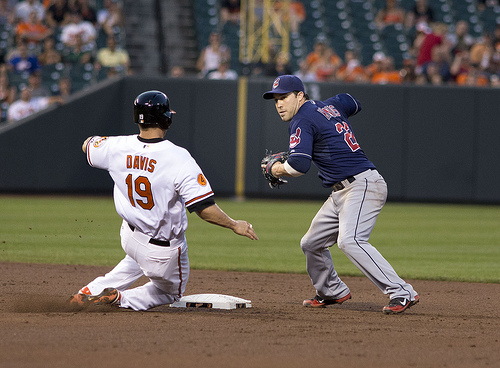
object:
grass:
[0, 190, 499, 285]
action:
[66, 73, 421, 316]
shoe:
[299, 288, 353, 310]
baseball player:
[257, 73, 421, 316]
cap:
[259, 73, 307, 101]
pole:
[232, 76, 249, 201]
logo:
[286, 126, 303, 149]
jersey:
[83, 132, 215, 242]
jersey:
[281, 92, 379, 190]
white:
[166, 291, 253, 312]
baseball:
[44, 55, 416, 332]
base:
[168, 291, 253, 310]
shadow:
[95, 301, 282, 321]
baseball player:
[62, 89, 258, 314]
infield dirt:
[0, 257, 499, 368]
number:
[123, 173, 138, 209]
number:
[130, 175, 155, 211]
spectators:
[0, 0, 499, 125]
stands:
[0, 1, 499, 133]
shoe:
[378, 289, 421, 316]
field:
[0, 190, 498, 367]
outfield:
[0, 190, 499, 286]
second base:
[0, 287, 251, 317]